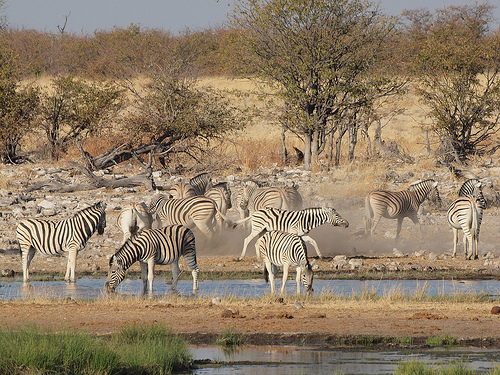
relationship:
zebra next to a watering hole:
[232, 204, 391, 267] [107, 259, 461, 329]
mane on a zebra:
[292, 234, 317, 264] [251, 221, 341, 301]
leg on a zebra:
[141, 254, 167, 296] [83, 223, 236, 297]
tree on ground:
[25, 141, 182, 210] [17, 194, 190, 218]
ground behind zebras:
[0, 72, 500, 279] [72, 171, 341, 256]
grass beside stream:
[50, 330, 193, 371] [199, 330, 404, 372]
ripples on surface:
[183, 345, 500, 374] [235, 328, 434, 371]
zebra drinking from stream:
[257, 230, 313, 296] [283, 260, 395, 306]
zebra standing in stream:
[16, 200, 108, 283] [15, 270, 259, 302]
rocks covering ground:
[33, 194, 96, 221] [6, 202, 99, 256]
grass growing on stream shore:
[387, 330, 477, 350] [331, 343, 491, 370]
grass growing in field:
[232, 128, 278, 178] [188, 141, 336, 193]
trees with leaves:
[0, 24, 500, 82] [132, 27, 178, 84]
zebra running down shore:
[232, 201, 361, 247] [204, 221, 439, 289]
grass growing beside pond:
[0, 319, 193, 374] [126, 313, 411, 373]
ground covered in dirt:
[234, 294, 498, 360] [339, 309, 392, 332]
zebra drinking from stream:
[249, 221, 321, 304] [0, 277, 500, 299]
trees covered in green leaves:
[52, 53, 257, 83] [113, 104, 169, 116]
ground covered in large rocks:
[235, 157, 310, 182] [205, 169, 377, 183]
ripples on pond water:
[271, 349, 438, 375] [201, 306, 417, 375]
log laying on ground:
[30, 164, 184, 197] [8, 135, 196, 223]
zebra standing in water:
[16, 176, 106, 331] [24, 254, 72, 334]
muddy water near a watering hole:
[205, 322, 485, 375] [263, 285, 486, 355]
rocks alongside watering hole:
[320, 254, 487, 277] [259, 177, 489, 346]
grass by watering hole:
[323, 281, 492, 328] [260, 292, 489, 314]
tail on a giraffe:
[352, 192, 382, 231] [350, 165, 442, 272]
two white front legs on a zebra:
[54, 231, 82, 310] [11, 217, 115, 357]